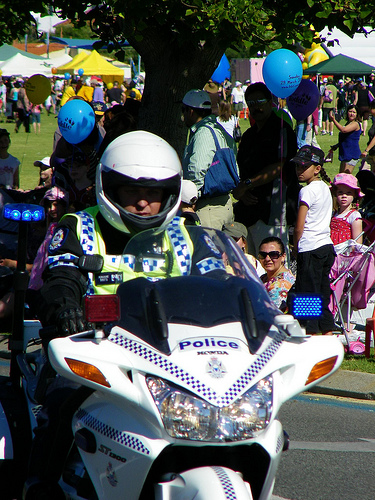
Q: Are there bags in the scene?
A: Yes, there is a bag.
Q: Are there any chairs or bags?
A: Yes, there is a bag.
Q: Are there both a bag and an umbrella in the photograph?
A: No, there is a bag but no umbrellas.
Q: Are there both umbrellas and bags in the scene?
A: No, there is a bag but no umbrellas.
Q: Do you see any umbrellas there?
A: No, there are no umbrellas.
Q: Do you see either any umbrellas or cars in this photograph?
A: No, there are no umbrellas or cars.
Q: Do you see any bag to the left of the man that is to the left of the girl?
A: Yes, there is a bag to the left of the man.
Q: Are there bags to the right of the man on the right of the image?
A: No, the bag is to the left of the man.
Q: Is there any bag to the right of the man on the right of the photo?
A: No, the bag is to the left of the man.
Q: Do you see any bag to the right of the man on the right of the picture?
A: No, the bag is to the left of the man.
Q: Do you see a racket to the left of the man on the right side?
A: No, there is a bag to the left of the man.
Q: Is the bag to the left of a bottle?
A: No, the bag is to the left of the man.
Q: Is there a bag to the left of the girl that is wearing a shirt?
A: Yes, there is a bag to the left of the girl.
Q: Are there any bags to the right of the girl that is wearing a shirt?
A: No, the bag is to the left of the girl.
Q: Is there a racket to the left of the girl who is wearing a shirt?
A: No, there is a bag to the left of the girl.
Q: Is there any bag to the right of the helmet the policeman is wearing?
A: Yes, there is a bag to the right of the helmet.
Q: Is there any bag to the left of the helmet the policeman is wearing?
A: No, the bag is to the right of the helmet.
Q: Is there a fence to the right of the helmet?
A: No, there is a bag to the right of the helmet.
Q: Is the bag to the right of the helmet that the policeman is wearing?
A: Yes, the bag is to the right of the helmet.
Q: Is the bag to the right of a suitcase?
A: No, the bag is to the right of the helmet.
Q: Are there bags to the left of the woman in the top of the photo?
A: Yes, there is a bag to the left of the woman.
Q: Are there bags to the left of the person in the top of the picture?
A: Yes, there is a bag to the left of the woman.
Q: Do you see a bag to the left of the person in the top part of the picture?
A: Yes, there is a bag to the left of the woman.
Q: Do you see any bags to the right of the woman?
A: No, the bag is to the left of the woman.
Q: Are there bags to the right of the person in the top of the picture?
A: No, the bag is to the left of the woman.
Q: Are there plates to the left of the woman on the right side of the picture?
A: No, there is a bag to the left of the woman.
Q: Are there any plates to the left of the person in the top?
A: No, there is a bag to the left of the woman.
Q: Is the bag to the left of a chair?
A: No, the bag is to the left of the woman.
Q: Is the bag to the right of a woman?
A: No, the bag is to the left of a woman.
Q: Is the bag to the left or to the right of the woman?
A: The bag is to the left of the woman.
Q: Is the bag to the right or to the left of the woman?
A: The bag is to the left of the woman.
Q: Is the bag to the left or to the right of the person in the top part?
A: The bag is to the left of the woman.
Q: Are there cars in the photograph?
A: No, there are no cars.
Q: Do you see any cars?
A: No, there are no cars.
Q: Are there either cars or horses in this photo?
A: No, there are no cars or horses.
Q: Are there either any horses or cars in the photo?
A: No, there are no cars or horses.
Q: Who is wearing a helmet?
A: The police officer is wearing a helmet.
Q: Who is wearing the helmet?
A: The police officer is wearing a helmet.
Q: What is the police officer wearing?
A: The police officer is wearing a helmet.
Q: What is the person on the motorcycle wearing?
A: The police officer is wearing a helmet.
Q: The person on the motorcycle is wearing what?
A: The police officer is wearing a helmet.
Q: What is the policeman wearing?
A: The police officer is wearing a helmet.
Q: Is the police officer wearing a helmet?
A: Yes, the police officer is wearing a helmet.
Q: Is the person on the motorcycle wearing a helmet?
A: Yes, the police officer is wearing a helmet.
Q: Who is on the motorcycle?
A: The police officer is on the motorbike.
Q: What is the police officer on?
A: The police officer is on the motorbike.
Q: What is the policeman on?
A: The police officer is on the motorbike.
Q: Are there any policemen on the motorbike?
A: Yes, there is a policeman on the motorbike.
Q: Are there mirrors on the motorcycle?
A: No, there is a policeman on the motorcycle.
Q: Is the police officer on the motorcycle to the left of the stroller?
A: Yes, the police officer is on the motorbike.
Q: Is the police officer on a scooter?
A: No, the police officer is on the motorbike.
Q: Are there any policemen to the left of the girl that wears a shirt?
A: Yes, there is a policeman to the left of the girl.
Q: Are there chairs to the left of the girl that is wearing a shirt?
A: No, there is a policeman to the left of the girl.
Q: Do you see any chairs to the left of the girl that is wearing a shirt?
A: No, there is a policeman to the left of the girl.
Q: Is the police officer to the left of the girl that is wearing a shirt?
A: Yes, the police officer is to the left of the girl.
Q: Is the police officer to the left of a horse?
A: No, the police officer is to the left of the girl.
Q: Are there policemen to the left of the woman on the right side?
A: Yes, there is a policeman to the left of the woman.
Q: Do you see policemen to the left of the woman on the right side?
A: Yes, there is a policeman to the left of the woman.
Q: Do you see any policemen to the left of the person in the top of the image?
A: Yes, there is a policeman to the left of the woman.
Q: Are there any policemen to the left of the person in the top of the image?
A: Yes, there is a policeman to the left of the woman.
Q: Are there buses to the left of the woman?
A: No, there is a policeman to the left of the woman.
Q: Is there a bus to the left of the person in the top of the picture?
A: No, there is a policeman to the left of the woman.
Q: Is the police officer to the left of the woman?
A: Yes, the police officer is to the left of the woman.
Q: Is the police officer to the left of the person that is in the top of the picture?
A: Yes, the police officer is to the left of the woman.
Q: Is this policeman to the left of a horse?
A: No, the policeman is to the left of the woman.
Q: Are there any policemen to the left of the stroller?
A: Yes, there is a policeman to the left of the stroller.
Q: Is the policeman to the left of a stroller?
A: Yes, the policeman is to the left of a stroller.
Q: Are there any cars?
A: No, there are no cars.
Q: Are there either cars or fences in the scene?
A: No, there are no cars or fences.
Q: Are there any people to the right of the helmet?
A: Yes, there is a person to the right of the helmet.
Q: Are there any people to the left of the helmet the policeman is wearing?
A: No, the person is to the right of the helmet.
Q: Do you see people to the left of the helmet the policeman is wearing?
A: No, the person is to the right of the helmet.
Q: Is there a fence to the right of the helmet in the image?
A: No, there is a person to the right of the helmet.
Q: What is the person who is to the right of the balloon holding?
A: The person is holding the bag.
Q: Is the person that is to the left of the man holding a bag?
A: Yes, the person is holding a bag.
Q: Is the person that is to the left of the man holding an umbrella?
A: No, the person is holding a bag.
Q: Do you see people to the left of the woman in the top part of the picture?
A: Yes, there is a person to the left of the woman.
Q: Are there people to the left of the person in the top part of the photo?
A: Yes, there is a person to the left of the woman.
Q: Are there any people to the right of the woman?
A: No, the person is to the left of the woman.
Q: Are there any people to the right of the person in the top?
A: No, the person is to the left of the woman.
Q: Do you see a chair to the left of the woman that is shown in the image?
A: No, there is a person to the left of the woman.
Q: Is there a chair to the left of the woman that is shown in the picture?
A: No, there is a person to the left of the woman.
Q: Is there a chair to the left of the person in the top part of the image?
A: No, there is a person to the left of the woman.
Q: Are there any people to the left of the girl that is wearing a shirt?
A: Yes, there is a person to the left of the girl.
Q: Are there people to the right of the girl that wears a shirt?
A: No, the person is to the left of the girl.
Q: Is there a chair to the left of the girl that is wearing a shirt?
A: No, there is a person to the left of the girl.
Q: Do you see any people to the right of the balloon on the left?
A: Yes, there is a person to the right of the balloon.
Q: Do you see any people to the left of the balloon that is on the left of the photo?
A: No, the person is to the right of the balloon.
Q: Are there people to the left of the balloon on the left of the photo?
A: No, the person is to the right of the balloon.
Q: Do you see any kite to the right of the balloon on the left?
A: No, there is a person to the right of the balloon.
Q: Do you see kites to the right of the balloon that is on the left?
A: No, there is a person to the right of the balloon.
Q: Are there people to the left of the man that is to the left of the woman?
A: Yes, there is a person to the left of the man.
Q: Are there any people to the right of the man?
A: No, the person is to the left of the man.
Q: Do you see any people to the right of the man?
A: No, the person is to the left of the man.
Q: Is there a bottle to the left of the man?
A: No, there is a person to the left of the man.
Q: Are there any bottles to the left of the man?
A: No, there is a person to the left of the man.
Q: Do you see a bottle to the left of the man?
A: No, there is a person to the left of the man.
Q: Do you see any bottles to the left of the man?
A: No, there is a person to the left of the man.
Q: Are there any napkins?
A: No, there are no napkins.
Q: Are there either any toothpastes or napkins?
A: No, there are no napkins or toothpastes.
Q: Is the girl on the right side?
A: Yes, the girl is on the right of the image.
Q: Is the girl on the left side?
A: No, the girl is on the right of the image.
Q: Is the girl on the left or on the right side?
A: The girl is on the right of the image.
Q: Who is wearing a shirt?
A: The girl is wearing a shirt.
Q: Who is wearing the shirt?
A: The girl is wearing a shirt.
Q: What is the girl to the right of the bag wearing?
A: The girl is wearing a shirt.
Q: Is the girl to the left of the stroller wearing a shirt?
A: Yes, the girl is wearing a shirt.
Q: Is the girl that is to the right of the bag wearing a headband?
A: No, the girl is wearing a shirt.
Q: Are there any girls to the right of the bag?
A: Yes, there is a girl to the right of the bag.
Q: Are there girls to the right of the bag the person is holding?
A: Yes, there is a girl to the right of the bag.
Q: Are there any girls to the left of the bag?
A: No, the girl is to the right of the bag.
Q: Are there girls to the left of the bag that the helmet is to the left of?
A: No, the girl is to the right of the bag.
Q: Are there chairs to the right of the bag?
A: No, there is a girl to the right of the bag.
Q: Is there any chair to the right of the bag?
A: No, there is a girl to the right of the bag.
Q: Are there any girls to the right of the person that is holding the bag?
A: Yes, there is a girl to the right of the person.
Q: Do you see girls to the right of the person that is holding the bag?
A: Yes, there is a girl to the right of the person.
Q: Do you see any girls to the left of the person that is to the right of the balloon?
A: No, the girl is to the right of the person.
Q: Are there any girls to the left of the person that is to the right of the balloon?
A: No, the girl is to the right of the person.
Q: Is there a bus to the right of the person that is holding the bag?
A: No, there is a girl to the right of the person.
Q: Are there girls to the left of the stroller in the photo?
A: Yes, there is a girl to the left of the stroller.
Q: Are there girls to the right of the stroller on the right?
A: No, the girl is to the left of the stroller.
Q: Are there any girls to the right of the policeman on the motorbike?
A: Yes, there is a girl to the right of the policeman.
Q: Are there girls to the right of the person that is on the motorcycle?
A: Yes, there is a girl to the right of the policeman.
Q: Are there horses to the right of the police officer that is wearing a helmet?
A: No, there is a girl to the right of the police officer.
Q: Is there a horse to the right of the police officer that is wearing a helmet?
A: No, there is a girl to the right of the police officer.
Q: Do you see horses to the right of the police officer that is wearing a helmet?
A: No, there is a girl to the right of the police officer.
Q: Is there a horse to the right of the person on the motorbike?
A: No, there is a girl to the right of the police officer.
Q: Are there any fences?
A: No, there are no fences.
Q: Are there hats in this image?
A: Yes, there is a hat.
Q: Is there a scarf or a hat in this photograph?
A: Yes, there is a hat.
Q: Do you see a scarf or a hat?
A: Yes, there is a hat.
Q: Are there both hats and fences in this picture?
A: No, there is a hat but no fences.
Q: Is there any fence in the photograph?
A: No, there are no fences.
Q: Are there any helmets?
A: Yes, there is a helmet.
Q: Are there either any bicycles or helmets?
A: Yes, there is a helmet.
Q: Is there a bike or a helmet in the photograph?
A: Yes, there is a helmet.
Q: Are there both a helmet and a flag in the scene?
A: No, there is a helmet but no flags.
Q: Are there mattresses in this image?
A: No, there are no mattresses.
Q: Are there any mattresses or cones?
A: No, there are no mattresses or cones.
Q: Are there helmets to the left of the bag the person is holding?
A: Yes, there is a helmet to the left of the bag.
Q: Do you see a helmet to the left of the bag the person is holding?
A: Yes, there is a helmet to the left of the bag.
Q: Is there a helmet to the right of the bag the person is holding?
A: No, the helmet is to the left of the bag.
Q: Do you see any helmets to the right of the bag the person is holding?
A: No, the helmet is to the left of the bag.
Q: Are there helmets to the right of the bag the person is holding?
A: No, the helmet is to the left of the bag.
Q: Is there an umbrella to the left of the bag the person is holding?
A: No, there is a helmet to the left of the bag.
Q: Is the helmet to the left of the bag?
A: Yes, the helmet is to the left of the bag.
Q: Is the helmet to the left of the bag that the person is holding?
A: Yes, the helmet is to the left of the bag.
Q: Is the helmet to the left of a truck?
A: No, the helmet is to the left of the bag.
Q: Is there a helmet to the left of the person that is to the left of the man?
A: Yes, there is a helmet to the left of the person.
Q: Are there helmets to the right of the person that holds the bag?
A: No, the helmet is to the left of the person.